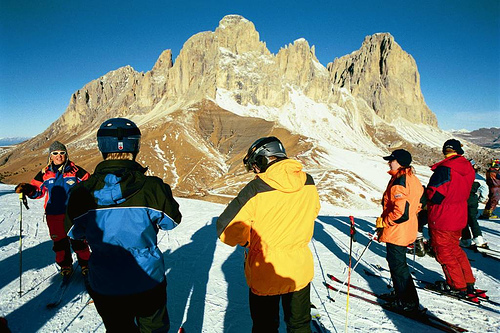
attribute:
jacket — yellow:
[228, 159, 328, 300]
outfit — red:
[425, 152, 483, 295]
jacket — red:
[24, 154, 94, 236]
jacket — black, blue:
[63, 154, 179, 304]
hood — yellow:
[242, 146, 312, 200]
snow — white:
[2, 181, 499, 331]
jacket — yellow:
[220, 152, 326, 295]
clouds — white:
[2, 101, 499, 186]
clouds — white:
[4, 107, 499, 150]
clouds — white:
[4, 101, 494, 141]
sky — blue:
[6, 4, 496, 111]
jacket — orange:
[378, 161, 421, 253]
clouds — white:
[6, 89, 498, 141]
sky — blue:
[2, 2, 496, 142]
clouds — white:
[4, 105, 499, 141]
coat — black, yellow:
[216, 152, 325, 306]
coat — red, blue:
[22, 157, 97, 227]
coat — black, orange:
[372, 161, 424, 244]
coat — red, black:
[426, 154, 473, 239]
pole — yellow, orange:
[333, 214, 367, 304]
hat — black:
[381, 137, 413, 167]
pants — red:
[432, 224, 473, 287]